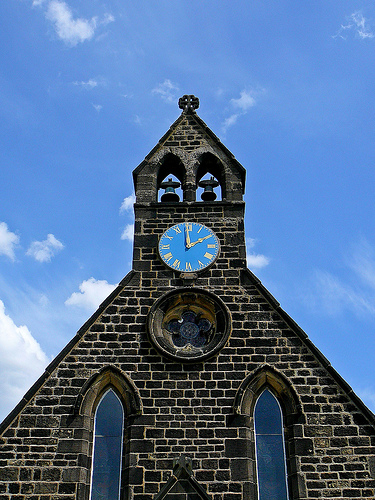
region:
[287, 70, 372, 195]
The clear blue sky.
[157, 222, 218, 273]
The clock on the tower.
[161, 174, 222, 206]
Two bells on the tower.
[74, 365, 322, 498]
Two church stain glass windows.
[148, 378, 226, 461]
The old brick work.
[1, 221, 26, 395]
Fluffy white clouds in the sky.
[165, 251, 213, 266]
The roman numerals on the clock.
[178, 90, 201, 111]
The steeple of the tower.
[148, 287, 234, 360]
A round decoration on the tower.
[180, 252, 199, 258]
The blue face of the clock.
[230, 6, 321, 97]
this is the sky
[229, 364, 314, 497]
this are windows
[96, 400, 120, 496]
this is a glass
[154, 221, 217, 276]
this is a clock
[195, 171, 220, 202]
this is a bell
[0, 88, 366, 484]
this is a building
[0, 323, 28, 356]
this is the cloud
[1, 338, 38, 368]
the clouds are white in color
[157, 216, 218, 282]
the clock surface is blue in color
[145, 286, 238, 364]
this is a decoration on the building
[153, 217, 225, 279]
large blue and yellow analog clock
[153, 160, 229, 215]
two large bells for ringing on the hour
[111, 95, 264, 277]
the top of a church; a steeple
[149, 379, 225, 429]
dark bricks on the side of the church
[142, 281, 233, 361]
the outside of a stained glass window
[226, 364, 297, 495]
the leftmost of a large window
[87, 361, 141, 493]
the rightmost of a large window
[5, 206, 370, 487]
The top of a church made of brick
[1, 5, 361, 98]
the background is made up of a blue sky and few clouds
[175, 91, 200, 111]
a sort of fluer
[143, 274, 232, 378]
window pane is sunken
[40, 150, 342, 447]
front of church with clock tower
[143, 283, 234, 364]
decorative flower design on front of building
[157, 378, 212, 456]
black brick front of building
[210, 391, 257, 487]
large black bricks around windows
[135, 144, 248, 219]
two bells in steeple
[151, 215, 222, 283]
blue clock face on top front of building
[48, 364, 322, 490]
two stained glass windows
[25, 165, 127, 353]
mostly blue sky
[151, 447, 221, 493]
decorative bird on front of building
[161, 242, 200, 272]
numbers on clock are gold